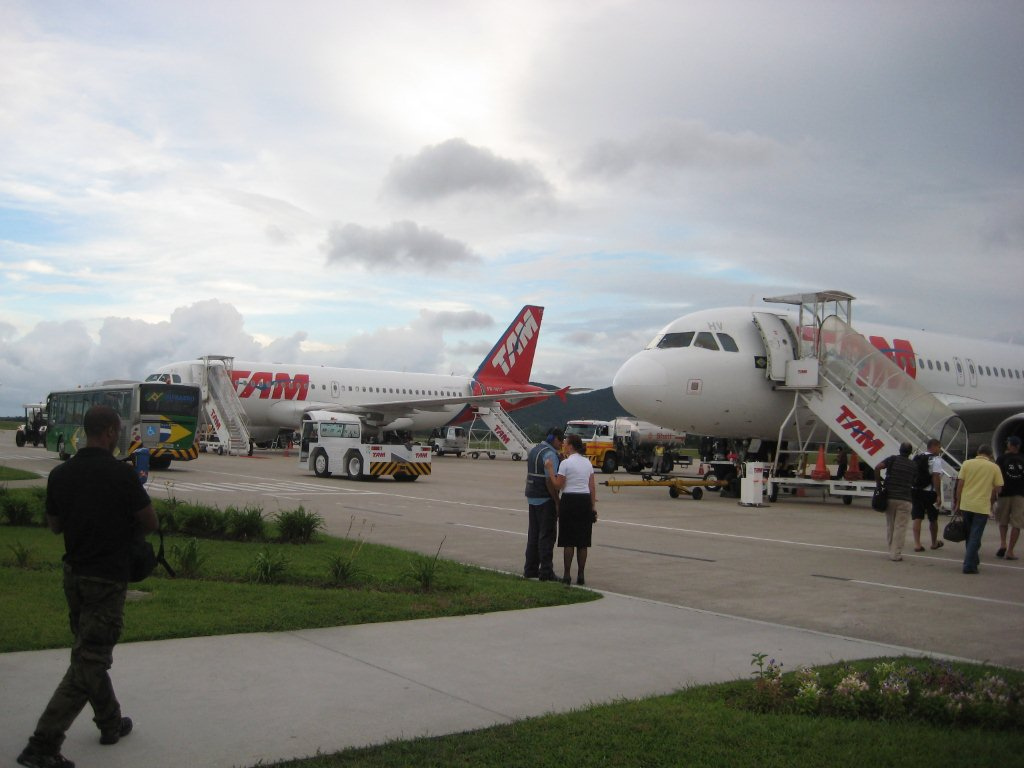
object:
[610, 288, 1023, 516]
plane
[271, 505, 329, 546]
bush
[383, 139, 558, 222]
cloud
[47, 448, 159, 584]
shirt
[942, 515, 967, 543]
bag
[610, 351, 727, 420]
nose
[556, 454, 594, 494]
shirt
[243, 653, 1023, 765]
grass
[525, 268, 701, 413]
cover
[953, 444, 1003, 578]
man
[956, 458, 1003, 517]
shirt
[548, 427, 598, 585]
woman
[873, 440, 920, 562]
man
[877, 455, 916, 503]
shirt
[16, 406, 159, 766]
man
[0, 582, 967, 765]
sidewalk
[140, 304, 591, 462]
airplane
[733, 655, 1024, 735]
flowers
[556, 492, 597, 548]
skirt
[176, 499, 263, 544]
bushes